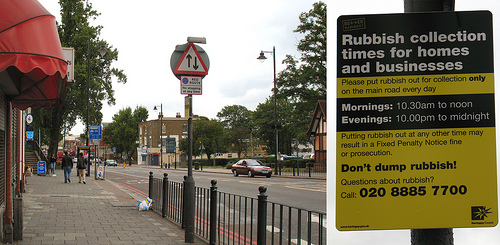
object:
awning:
[0, 1, 71, 108]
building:
[0, 2, 25, 244]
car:
[231, 159, 273, 178]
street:
[219, 167, 436, 244]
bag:
[138, 196, 153, 211]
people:
[60, 152, 75, 184]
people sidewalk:
[56, 187, 150, 241]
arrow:
[186, 54, 193, 68]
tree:
[180, 119, 229, 166]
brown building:
[136, 113, 225, 167]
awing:
[0, 0, 66, 107]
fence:
[147, 172, 324, 244]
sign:
[335, 10, 499, 231]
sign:
[181, 75, 202, 95]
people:
[77, 152, 88, 183]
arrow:
[192, 56, 199, 70]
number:
[359, 185, 467, 198]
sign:
[176, 42, 209, 75]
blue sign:
[89, 125, 102, 139]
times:
[341, 113, 489, 125]